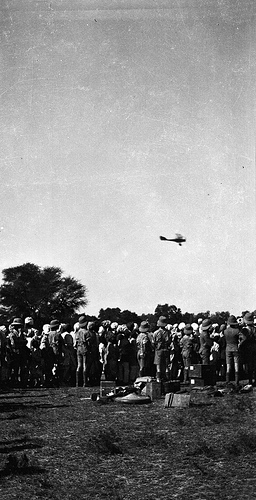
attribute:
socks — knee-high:
[75, 371, 79, 383]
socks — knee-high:
[82, 372, 86, 382]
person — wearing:
[152, 315, 171, 383]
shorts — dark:
[77, 342, 87, 363]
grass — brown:
[3, 385, 247, 499]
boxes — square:
[186, 363, 216, 387]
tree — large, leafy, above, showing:
[3, 258, 88, 326]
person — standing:
[220, 315, 244, 377]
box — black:
[186, 362, 214, 377]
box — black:
[189, 378, 216, 389]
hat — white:
[172, 322, 182, 330]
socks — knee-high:
[72, 365, 100, 392]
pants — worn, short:
[220, 344, 241, 363]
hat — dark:
[155, 313, 167, 329]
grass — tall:
[77, 420, 138, 459]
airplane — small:
[161, 231, 186, 245]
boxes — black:
[129, 373, 185, 395]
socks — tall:
[212, 357, 250, 383]